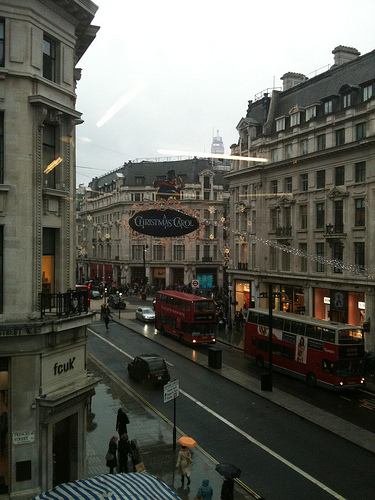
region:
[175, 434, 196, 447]
an orange umbrella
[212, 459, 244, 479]
a black umbrella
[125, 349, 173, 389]
a black car on the road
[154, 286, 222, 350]
a red double level bus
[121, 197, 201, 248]
a large black sign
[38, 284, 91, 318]
a black metal railing on a balcony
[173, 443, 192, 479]
a white duster coat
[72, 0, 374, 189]
a bright gray sky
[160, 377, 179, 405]
a white street sign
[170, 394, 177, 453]
a black sign post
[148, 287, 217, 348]
a red double-decker bus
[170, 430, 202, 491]
a woman with an orange umbrella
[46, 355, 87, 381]
a sign that says fcuk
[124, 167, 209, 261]
A Christmas Carol sign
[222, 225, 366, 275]
a few strands of Christmas lights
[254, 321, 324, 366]
advertisement on the side of a bus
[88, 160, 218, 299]
a building in the background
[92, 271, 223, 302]
a group of people in front of a story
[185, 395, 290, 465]
a white line on a street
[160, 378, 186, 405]
a sign on the side of a road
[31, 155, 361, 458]
commercial street in city on rainy day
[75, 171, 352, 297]
elevated holiday decorations over street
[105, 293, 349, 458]
thin and long island in middle of road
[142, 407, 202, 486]
pedestrian with yellow umbrella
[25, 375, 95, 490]
doorway set at an angle in building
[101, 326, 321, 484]
white line going down street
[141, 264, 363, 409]
double-decker buses on one side of the road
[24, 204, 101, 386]
railing and small terrace above sign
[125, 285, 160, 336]
car with bright headlights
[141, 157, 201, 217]
image of man on top of building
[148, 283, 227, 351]
bus on a street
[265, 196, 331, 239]
windows on a building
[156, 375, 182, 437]
sign on a pole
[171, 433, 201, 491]
person with orange umbrella walking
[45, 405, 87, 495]
door of a building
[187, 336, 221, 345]
front headlights on a vehicle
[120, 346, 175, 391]
car in a street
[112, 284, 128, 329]
street light on a sidewalk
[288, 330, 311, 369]
advertising sign on a bus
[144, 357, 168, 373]
rear window on a car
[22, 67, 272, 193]
reflection of lights in glass of room in which photograph was taken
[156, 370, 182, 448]
sign on a tall pole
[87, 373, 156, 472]
people on the sidewalk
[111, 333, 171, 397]
small dark vehicle driving on the road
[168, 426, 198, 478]
person holding an orange umbrella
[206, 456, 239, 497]
person holding a black umbrella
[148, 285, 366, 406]
two two-story buses on the street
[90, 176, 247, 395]
festive sign above the street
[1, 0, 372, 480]
large buildings along both sides of the street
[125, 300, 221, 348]
small grey vehicle behind bus